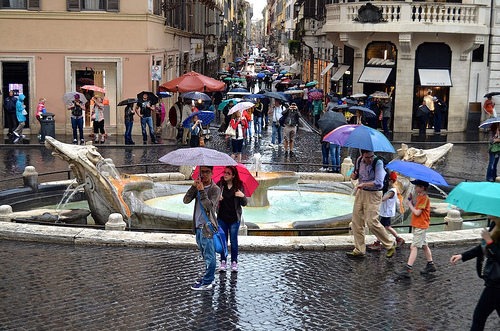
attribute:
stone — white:
[267, 0, 484, 128]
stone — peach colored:
[1, 2, 204, 113]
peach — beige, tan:
[1, 2, 214, 138]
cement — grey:
[30, 132, 164, 234]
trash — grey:
[37, 110, 61, 143]